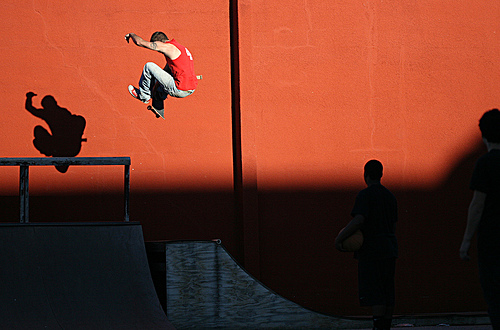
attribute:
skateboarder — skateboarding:
[126, 31, 201, 120]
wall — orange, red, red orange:
[1, 8, 498, 309]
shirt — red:
[159, 40, 197, 91]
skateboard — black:
[149, 82, 166, 120]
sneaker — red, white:
[127, 86, 148, 103]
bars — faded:
[0, 153, 131, 168]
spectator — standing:
[335, 158, 401, 327]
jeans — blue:
[478, 229, 500, 323]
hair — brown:
[150, 31, 167, 41]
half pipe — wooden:
[144, 236, 355, 329]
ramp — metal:
[1, 155, 176, 329]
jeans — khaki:
[135, 63, 194, 112]